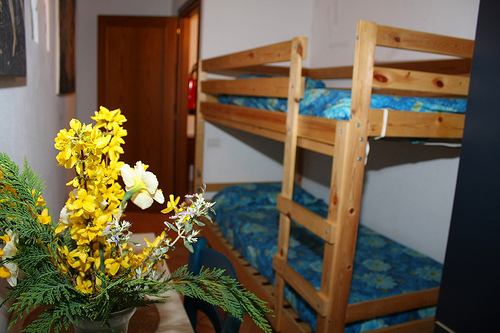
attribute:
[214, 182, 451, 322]
sheets — blue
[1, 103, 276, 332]
flower — yellow, white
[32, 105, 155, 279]
flowers — nice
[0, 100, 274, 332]
flowers — beautiful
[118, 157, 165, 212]
rose — white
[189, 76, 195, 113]
extinguisher — red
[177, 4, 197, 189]
doorway — opened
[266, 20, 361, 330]
ladder — wooden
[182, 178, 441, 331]
bed spread — blue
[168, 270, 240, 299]
leaves — green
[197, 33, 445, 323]
beds — wooden, bunk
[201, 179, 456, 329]
bed — made up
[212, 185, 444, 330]
bedspread — blue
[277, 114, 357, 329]
ladder — wooden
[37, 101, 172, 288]
flowers — yellow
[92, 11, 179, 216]
door — open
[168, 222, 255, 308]
leaves — green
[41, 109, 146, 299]
flower — yellow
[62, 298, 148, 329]
vase — glass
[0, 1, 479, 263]
white wall — painted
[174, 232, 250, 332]
chair — blue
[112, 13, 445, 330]
bedroom — pictured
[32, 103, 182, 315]
flowers — yellow, bouquet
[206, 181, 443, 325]
bed spread — floral